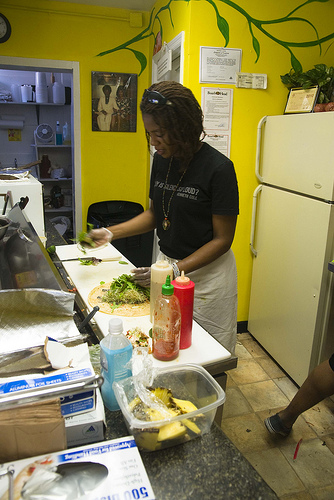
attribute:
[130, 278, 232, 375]
sauce — hot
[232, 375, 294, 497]
floor — tiled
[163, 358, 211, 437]
dish — plastic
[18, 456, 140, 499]
bags — plastic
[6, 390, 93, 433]
bags — paper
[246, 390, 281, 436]
shoe — black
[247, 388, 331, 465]
foot — lifting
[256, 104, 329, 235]
refrigerator — here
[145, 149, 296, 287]
shirt — black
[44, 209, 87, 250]
fan — here, white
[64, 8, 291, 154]
wall — yellow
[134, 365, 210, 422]
container — transparent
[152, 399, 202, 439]
pineapples — large, yellow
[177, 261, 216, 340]
bottle — red, empty, condiment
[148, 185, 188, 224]
necklace — long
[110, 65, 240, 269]
woman — black, preparing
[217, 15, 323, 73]
leaves — green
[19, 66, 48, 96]
cups — white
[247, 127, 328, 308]
door — closed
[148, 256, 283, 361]
apron — beige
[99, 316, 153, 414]
water — blue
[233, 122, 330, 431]
refrigerator — white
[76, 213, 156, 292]
gloves — plastic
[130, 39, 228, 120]
door — wooden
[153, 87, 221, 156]
hair — brown